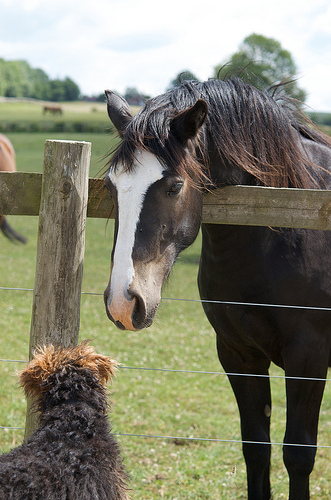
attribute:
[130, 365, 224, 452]
grass — green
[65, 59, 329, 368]
horse — curious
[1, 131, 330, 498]
grass — green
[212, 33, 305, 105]
leaves — green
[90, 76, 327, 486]
horse — black, white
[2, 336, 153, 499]
small dog — haired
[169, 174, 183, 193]
eye — black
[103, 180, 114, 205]
eye — black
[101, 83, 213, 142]
ears — perked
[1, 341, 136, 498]
dog — black, brown, fuzzy, headed, curious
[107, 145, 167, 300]
stripe — white